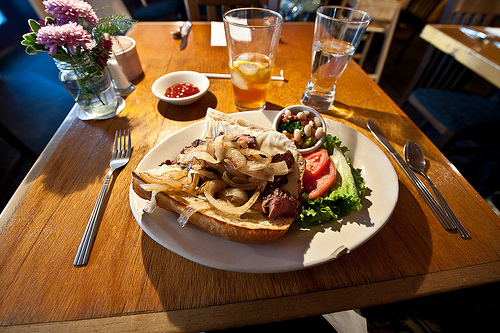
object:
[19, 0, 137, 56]
flowers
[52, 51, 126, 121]
vase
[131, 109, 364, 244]
food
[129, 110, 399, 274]
plate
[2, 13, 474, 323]
table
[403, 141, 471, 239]
spoon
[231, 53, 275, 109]
liquid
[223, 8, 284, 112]
glass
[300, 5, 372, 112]
water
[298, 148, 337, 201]
tomatoes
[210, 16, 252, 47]
napkin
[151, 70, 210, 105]
bowl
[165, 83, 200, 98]
ketchup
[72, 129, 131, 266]
fork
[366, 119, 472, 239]
knife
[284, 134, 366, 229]
lettuce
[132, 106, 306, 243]
sandwich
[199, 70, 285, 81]
straw